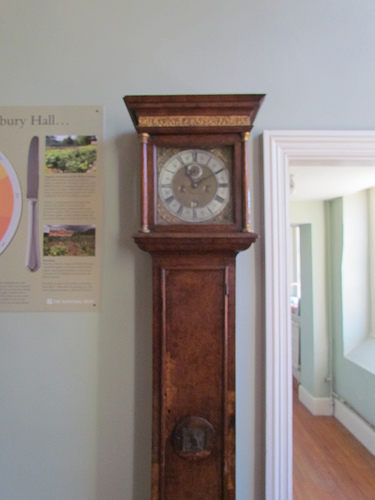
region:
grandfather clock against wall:
[107, 60, 272, 481]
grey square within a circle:
[170, 407, 215, 467]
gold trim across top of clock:
[131, 105, 247, 127]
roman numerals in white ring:
[153, 144, 236, 219]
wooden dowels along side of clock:
[126, 124, 253, 240]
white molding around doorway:
[255, 120, 341, 424]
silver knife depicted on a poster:
[20, 95, 57, 283]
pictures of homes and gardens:
[37, 123, 100, 266]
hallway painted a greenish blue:
[296, 177, 362, 484]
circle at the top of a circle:
[168, 142, 214, 187]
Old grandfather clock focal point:
[125, 86, 267, 497]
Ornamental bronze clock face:
[153, 146, 237, 225]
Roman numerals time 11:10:
[171, 148, 229, 192]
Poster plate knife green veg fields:
[1, 98, 110, 321]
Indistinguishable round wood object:
[161, 400, 231, 479]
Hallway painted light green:
[289, 173, 369, 497]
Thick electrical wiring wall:
[322, 192, 367, 417]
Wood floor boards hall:
[292, 404, 373, 494]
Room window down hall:
[287, 217, 303, 380]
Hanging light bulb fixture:
[282, 165, 305, 200]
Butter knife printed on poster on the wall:
[21, 131, 42, 276]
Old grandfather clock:
[117, 84, 271, 498]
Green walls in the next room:
[286, 190, 373, 424]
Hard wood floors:
[289, 375, 373, 497]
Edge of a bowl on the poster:
[0, 146, 21, 263]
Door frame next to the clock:
[262, 123, 372, 496]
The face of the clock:
[157, 147, 233, 221]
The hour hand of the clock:
[180, 159, 198, 191]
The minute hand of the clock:
[191, 167, 227, 186]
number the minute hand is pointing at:
[213, 163, 226, 178]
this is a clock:
[138, 112, 257, 473]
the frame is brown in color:
[130, 95, 252, 145]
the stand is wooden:
[160, 276, 226, 490]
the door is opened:
[285, 135, 372, 494]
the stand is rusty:
[160, 329, 231, 494]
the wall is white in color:
[4, 0, 369, 84]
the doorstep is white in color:
[266, 140, 287, 492]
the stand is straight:
[157, 258, 234, 499]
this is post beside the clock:
[2, 108, 103, 309]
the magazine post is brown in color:
[0, 112, 95, 310]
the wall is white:
[57, 19, 138, 74]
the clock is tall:
[122, 77, 251, 497]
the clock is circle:
[158, 138, 238, 229]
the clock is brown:
[117, 71, 261, 486]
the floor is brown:
[299, 422, 356, 498]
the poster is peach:
[4, 80, 116, 321]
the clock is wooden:
[124, 66, 267, 496]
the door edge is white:
[264, 133, 306, 491]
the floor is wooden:
[301, 437, 337, 492]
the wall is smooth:
[80, 22, 260, 70]